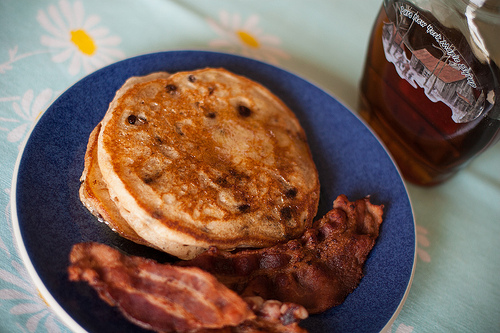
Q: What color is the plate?
A: Blue.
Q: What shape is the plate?
A: Circle.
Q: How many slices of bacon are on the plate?
A: Two.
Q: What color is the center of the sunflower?
A: Yellow.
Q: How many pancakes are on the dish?
A: Two.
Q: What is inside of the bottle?
A: Syrup.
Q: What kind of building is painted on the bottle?
A: Cabin.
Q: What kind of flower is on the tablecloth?
A: Sunflower.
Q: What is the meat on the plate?
A: Bacon.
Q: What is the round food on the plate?
A: Pancake.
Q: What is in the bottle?
A: Syrup.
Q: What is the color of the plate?
A: Blue.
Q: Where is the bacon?
A: On a plate.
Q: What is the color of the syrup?
A: Brown.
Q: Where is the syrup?
A: In a bottle.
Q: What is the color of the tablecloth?
A: Blue.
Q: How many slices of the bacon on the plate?
A: Two.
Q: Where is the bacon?
A: On the plate.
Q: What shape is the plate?
A: Round.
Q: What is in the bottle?
A: Syrup.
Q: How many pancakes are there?
A: 2.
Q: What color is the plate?
A: Blue.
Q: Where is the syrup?
A: To the right of the plate.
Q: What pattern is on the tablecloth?
A: Flowers.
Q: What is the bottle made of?
A: Glass.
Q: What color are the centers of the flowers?
A: Yellow.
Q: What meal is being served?
A: Breakfast.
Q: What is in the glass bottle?
A: Maple syrup.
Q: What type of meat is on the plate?
A: Bacon.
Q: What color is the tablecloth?
A: Baby blue.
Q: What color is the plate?
A: Blue.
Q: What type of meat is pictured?
A: Bacon.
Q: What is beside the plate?
A: Syrup.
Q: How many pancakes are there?
A: Two.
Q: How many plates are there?
A: One.